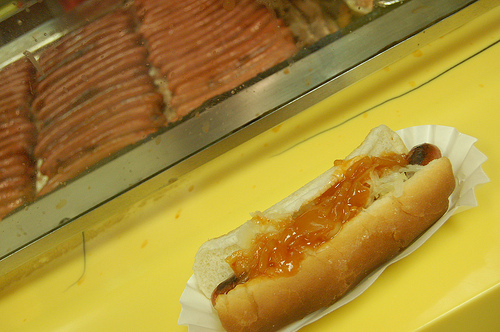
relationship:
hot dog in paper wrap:
[206, 138, 448, 310] [453, 127, 488, 209]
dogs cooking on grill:
[7, 5, 305, 190] [0, 0, 469, 265]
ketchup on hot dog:
[231, 207, 338, 271] [405, 141, 433, 167]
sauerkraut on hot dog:
[254, 190, 380, 261] [195, 137, 457, 321]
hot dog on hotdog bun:
[189, 111, 453, 322] [186, 122, 461, 332]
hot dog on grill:
[0, 0, 305, 222] [25, 51, 234, 250]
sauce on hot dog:
[250, 227, 307, 274] [166, 115, 386, 325]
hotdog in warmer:
[43, 122, 121, 160] [69, 62, 194, 202]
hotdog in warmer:
[41, 91, 104, 128] [69, 62, 194, 202]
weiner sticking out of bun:
[79, 74, 472, 311] [263, 267, 354, 301]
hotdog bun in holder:
[186, 123, 444, 330] [176, 121, 494, 332]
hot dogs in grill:
[193, 116, 465, 321] [58, 57, 177, 195]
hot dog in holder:
[206, 138, 448, 310] [176, 121, 494, 332]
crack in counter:
[60, 227, 93, 294] [5, 0, 497, 327]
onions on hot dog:
[220, 154, 427, 269] [227, 144, 447, 288]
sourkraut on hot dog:
[363, 159, 433, 206] [227, 144, 447, 288]